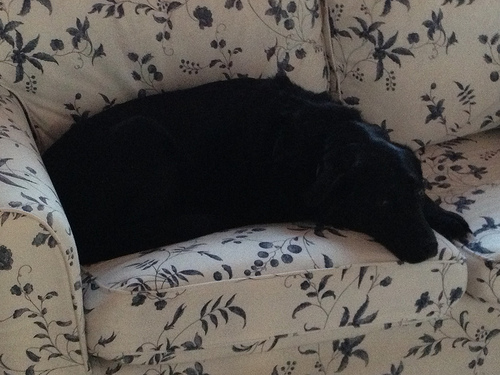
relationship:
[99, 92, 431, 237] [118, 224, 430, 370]
dog on cushion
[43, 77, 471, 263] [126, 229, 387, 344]
dog on cushion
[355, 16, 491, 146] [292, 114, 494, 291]
cushion by head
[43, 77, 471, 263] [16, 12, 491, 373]
dog on top of couch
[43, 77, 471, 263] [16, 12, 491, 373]
dog laying on couch